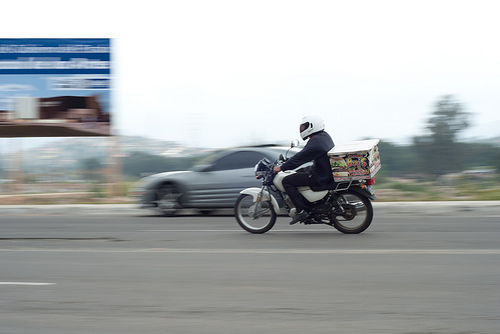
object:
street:
[0, 205, 499, 334]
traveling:
[0, 207, 499, 333]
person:
[270, 114, 334, 222]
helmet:
[299, 112, 326, 140]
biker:
[275, 116, 335, 225]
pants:
[281, 170, 329, 214]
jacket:
[280, 132, 336, 192]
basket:
[327, 139, 383, 181]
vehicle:
[133, 143, 304, 215]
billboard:
[0, 36, 111, 138]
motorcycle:
[235, 141, 382, 237]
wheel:
[234, 188, 279, 234]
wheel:
[326, 187, 375, 232]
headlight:
[251, 157, 268, 176]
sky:
[2, 1, 500, 148]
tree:
[411, 93, 472, 177]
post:
[106, 137, 121, 207]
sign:
[0, 38, 113, 138]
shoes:
[291, 205, 311, 224]